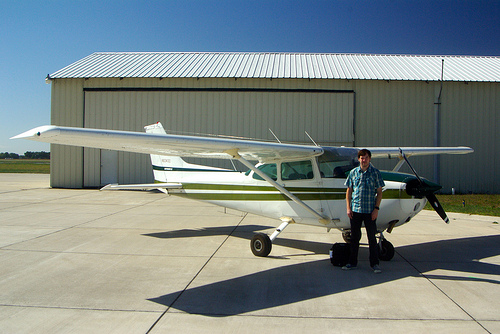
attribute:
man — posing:
[331, 145, 384, 275]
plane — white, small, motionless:
[29, 102, 471, 275]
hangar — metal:
[54, 43, 492, 191]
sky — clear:
[146, 6, 314, 53]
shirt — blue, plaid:
[346, 166, 379, 218]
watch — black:
[375, 205, 386, 211]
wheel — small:
[241, 228, 273, 263]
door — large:
[81, 84, 362, 179]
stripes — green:
[163, 176, 422, 205]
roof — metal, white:
[61, 48, 499, 75]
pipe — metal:
[426, 87, 443, 189]